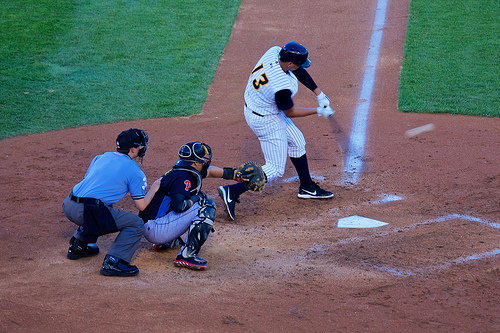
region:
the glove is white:
[297, 85, 339, 113]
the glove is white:
[303, 97, 357, 155]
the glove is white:
[309, 71, 343, 126]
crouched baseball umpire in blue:
[53, 116, 165, 291]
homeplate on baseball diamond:
[329, 203, 401, 244]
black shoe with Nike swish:
[293, 177, 340, 204]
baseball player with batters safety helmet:
[234, 31, 366, 219]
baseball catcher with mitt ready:
[147, 121, 270, 286]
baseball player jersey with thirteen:
[226, 32, 318, 124]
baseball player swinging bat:
[212, 21, 372, 232]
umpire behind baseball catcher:
[47, 122, 284, 293]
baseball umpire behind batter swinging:
[144, 23, 375, 275]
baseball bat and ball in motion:
[307, 77, 457, 190]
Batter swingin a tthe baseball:
[247, 42, 439, 215]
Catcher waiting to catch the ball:
[160, 121, 272, 291]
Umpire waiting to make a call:
[64, 98, 138, 273]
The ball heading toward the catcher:
[367, 67, 442, 188]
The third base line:
[341, 11, 401, 196]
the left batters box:
[302, 231, 497, 290]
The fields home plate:
[327, 204, 397, 241]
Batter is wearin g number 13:
[235, 51, 283, 111]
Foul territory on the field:
[27, 5, 252, 110]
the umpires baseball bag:
[70, 196, 120, 245]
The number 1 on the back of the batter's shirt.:
[247, 63, 271, 76]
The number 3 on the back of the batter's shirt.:
[248, 74, 271, 88]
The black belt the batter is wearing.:
[241, 97, 266, 116]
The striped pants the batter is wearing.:
[239, 102, 306, 171]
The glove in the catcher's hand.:
[233, 160, 274, 198]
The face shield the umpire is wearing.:
[129, 126, 156, 158]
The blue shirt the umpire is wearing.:
[67, 152, 147, 207]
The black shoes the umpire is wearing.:
[62, 242, 153, 288]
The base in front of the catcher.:
[314, 205, 379, 234]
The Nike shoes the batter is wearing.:
[212, 177, 342, 223]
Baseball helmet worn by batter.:
[273, 40, 315, 72]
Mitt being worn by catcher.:
[233, 161, 269, 196]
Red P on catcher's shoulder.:
[172, 177, 197, 195]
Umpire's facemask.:
[135, 125, 153, 161]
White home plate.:
[333, 199, 388, 237]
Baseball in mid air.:
[397, 112, 435, 147]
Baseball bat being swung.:
[320, 111, 375, 174]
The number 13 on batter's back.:
[245, 60, 269, 97]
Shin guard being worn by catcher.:
[175, 196, 216, 256]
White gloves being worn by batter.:
[315, 88, 332, 119]